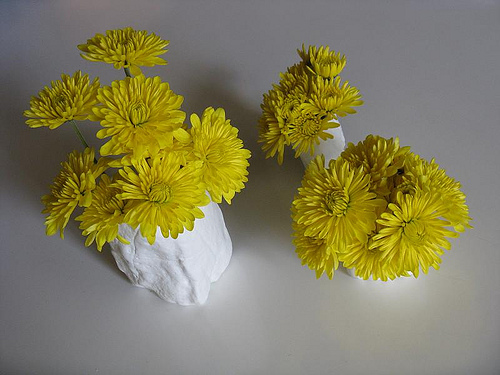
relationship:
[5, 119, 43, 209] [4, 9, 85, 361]
shadow on table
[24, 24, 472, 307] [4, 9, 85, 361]
flowers are on table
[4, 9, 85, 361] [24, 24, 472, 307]
table beneath flowers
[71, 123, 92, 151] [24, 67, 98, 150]
stem of flower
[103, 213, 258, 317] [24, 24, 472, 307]
vase for flowers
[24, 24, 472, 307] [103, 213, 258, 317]
flowers in vase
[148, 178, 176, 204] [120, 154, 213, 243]
center of flower